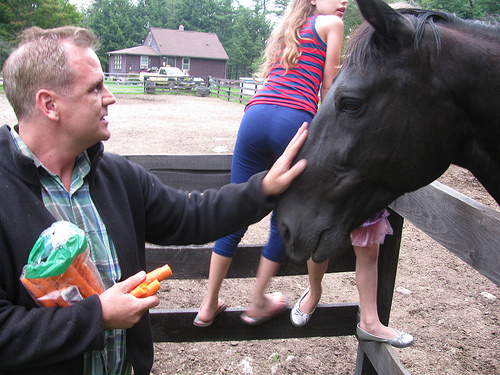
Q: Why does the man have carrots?
A: To feed the horse.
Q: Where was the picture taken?
A: Horse farm.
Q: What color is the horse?
A: Brown.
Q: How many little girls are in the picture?
A: Two.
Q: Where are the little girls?
A: On fence.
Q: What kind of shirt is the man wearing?
A: Plaid.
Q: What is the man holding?
A: Carrots.